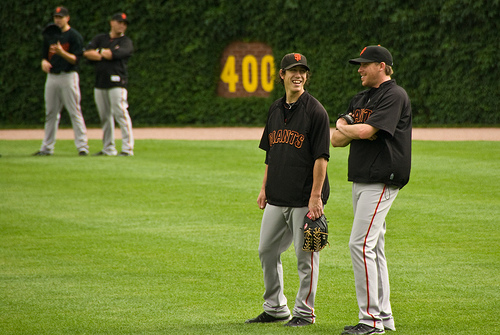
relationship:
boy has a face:
[248, 49, 333, 326] [282, 68, 310, 92]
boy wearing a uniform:
[248, 49, 333, 326] [254, 94, 331, 322]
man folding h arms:
[83, 9, 136, 157] [83, 45, 124, 64]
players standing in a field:
[32, 4, 408, 335] [1, 0, 500, 334]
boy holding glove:
[248, 49, 333, 326] [303, 212, 329, 250]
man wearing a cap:
[83, 9, 136, 157] [109, 11, 133, 25]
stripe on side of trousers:
[70, 73, 85, 130] [41, 72, 91, 151]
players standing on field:
[32, 4, 408, 335] [1, 0, 500, 334]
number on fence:
[219, 53, 275, 94] [1, 1, 500, 127]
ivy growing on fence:
[1, 1, 500, 128] [1, 1, 500, 127]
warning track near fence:
[1, 127, 500, 140] [1, 1, 500, 127]